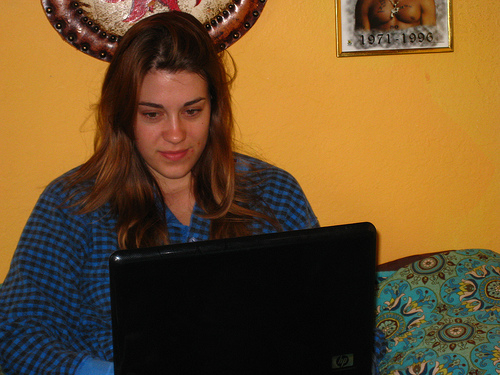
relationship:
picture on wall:
[332, 0, 454, 59] [1, 1, 484, 281]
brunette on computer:
[0, 10, 389, 374] [108, 221, 380, 374]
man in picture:
[354, 1, 436, 34] [335, 0, 454, 57]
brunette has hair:
[0, 10, 389, 374] [38, 9, 285, 251]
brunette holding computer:
[0, 10, 389, 374] [108, 221, 380, 374]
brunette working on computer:
[0, 10, 389, 374] [108, 221, 380, 374]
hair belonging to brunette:
[38, 9, 285, 251] [0, 10, 389, 374]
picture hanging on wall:
[332, 0, 454, 59] [1, 1, 484, 281]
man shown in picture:
[354, 1, 436, 34] [332, 0, 454, 59]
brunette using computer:
[0, 10, 389, 374] [148, 239, 335, 360]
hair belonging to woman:
[38, 9, 285, 251] [2, 9, 389, 373]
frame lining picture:
[331, 1, 470, 65] [332, 0, 454, 59]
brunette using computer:
[15, 13, 437, 373] [107, 221, 379, 373]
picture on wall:
[335, 0, 454, 57] [272, 3, 493, 247]